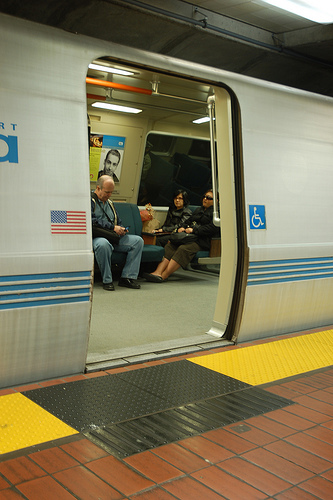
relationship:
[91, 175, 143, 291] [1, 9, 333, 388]
man inside train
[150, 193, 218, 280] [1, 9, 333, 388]
person inside train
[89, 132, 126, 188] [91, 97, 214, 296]
poster in background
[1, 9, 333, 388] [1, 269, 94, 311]
train has stripe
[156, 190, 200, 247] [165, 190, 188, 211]
woman has hair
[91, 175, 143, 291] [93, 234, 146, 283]
man wearing jeans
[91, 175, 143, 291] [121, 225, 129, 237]
man looking at phone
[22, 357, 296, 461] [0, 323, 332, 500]
mat on ground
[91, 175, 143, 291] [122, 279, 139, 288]
man wearing shoe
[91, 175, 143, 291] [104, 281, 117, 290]
man wearing shoe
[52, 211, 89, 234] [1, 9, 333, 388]
flag on train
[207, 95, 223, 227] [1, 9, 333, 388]
pole inside train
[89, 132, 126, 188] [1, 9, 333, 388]
poster inside train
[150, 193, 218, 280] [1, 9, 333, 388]
person on train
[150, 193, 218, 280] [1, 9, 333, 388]
person relaxing in train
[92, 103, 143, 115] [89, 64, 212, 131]
fixture on ceiling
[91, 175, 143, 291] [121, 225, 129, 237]
man using phone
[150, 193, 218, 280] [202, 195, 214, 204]
person wearing sunglasses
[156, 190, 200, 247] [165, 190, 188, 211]
woman with hair